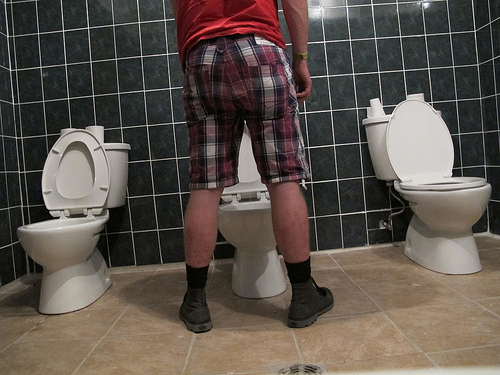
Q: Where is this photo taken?
A: Bathroom.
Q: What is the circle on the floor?
A: A drain.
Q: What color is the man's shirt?
A: Red.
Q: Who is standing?
A: A man.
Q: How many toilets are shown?
A: Three.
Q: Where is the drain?
A: On the floor.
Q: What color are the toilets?
A: White.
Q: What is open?
A: The toilets.